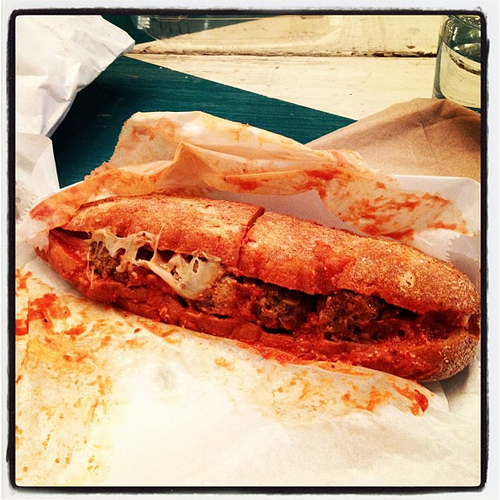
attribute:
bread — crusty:
[107, 163, 469, 314]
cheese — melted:
[86, 225, 225, 298]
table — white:
[55, 15, 449, 192]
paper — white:
[15, 13, 139, 248]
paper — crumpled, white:
[178, 116, 498, 246]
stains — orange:
[32, 283, 132, 452]